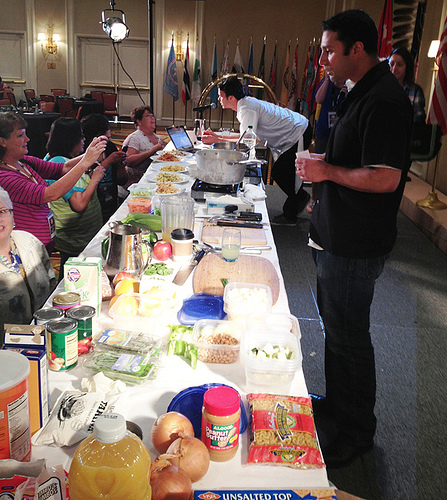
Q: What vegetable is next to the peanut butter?
A: Onion.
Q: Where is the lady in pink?
A: On the left.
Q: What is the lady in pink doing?
A: Taking a picture.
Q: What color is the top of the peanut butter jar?
A: Red.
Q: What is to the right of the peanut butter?
A: Pasta.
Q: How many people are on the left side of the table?
A: Five.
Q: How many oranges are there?
A: Three.